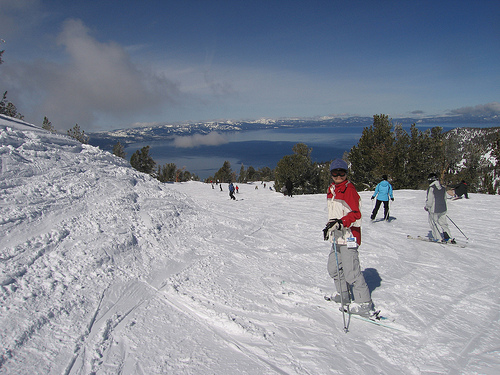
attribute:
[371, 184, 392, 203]
jacket — blue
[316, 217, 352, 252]
hand — gloved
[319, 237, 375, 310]
grey pants — gray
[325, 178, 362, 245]
jacket — red and white, white and red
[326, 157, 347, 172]
hat — blue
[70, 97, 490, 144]
mountains — snow capped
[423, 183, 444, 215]
jacket — grey, white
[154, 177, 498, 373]
field — snow-covered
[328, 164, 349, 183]
goggles — black